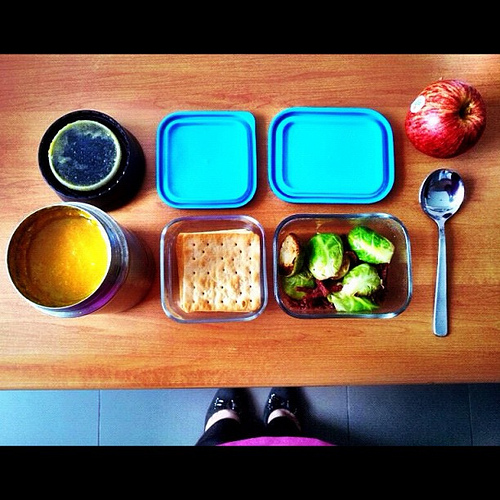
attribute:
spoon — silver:
[416, 166, 473, 343]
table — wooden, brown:
[1, 47, 498, 392]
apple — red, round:
[401, 80, 483, 162]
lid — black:
[31, 119, 123, 181]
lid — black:
[34, 106, 147, 211]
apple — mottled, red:
[406, 71, 476, 159]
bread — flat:
[175, 231, 262, 316]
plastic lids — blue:
[145, 100, 407, 211]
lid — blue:
[151, 115, 263, 211]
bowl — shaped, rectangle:
[265, 208, 436, 325]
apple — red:
[397, 75, 494, 159]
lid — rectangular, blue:
[269, 106, 397, 206]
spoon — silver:
[418, 169, 465, 339]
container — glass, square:
[159, 212, 268, 322]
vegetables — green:
[282, 225, 394, 310]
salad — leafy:
[289, 229, 394, 309]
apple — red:
[398, 74, 483, 159]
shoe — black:
[202, 386, 256, 428]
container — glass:
[270, 211, 413, 321]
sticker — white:
[408, 94, 427, 114]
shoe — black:
[258, 386, 302, 427]